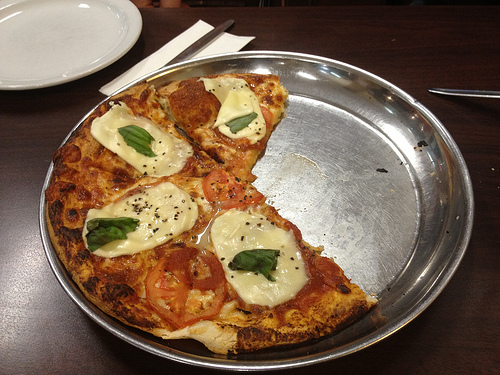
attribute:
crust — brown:
[263, 297, 373, 345]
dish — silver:
[31, 40, 481, 370]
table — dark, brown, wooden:
[13, 21, 495, 371]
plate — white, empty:
[0, 3, 139, 83]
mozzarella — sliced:
[205, 201, 319, 296]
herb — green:
[232, 246, 281, 280]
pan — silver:
[44, 54, 477, 373]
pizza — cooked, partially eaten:
[42, 60, 404, 340]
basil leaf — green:
[228, 247, 284, 282]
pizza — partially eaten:
[38, 62, 383, 355]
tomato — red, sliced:
[143, 241, 235, 324]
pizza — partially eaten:
[52, 75, 361, 338]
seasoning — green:
[131, 193, 154, 219]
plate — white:
[4, 4, 143, 88]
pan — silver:
[334, 144, 429, 194]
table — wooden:
[437, 302, 489, 368]